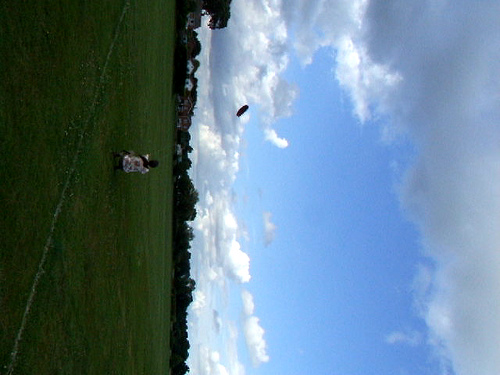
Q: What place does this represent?
A: It represents the field.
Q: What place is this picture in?
A: It is at the field.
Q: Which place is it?
A: It is a field.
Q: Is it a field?
A: Yes, it is a field.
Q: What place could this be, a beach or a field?
A: It is a field.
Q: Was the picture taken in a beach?
A: No, the picture was taken in a field.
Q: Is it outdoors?
A: Yes, it is outdoors.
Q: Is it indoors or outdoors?
A: It is outdoors.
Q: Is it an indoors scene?
A: No, it is outdoors.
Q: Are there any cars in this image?
A: No, there are no cars.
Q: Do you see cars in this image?
A: No, there are no cars.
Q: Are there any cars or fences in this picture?
A: No, there are no cars or fences.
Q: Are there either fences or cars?
A: No, there are no cars or fences.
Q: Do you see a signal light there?
A: No, there are no traffic lights.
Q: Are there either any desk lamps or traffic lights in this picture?
A: No, there are no traffic lights or desk lamps.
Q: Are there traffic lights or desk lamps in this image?
A: No, there are no traffic lights or desk lamps.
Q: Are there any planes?
A: No, there are no planes.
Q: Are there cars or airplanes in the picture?
A: No, there are no airplanes or cars.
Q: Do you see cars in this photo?
A: No, there are no cars.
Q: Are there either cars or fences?
A: No, there are no cars or fences.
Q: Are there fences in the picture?
A: No, there are no fences.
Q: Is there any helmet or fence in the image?
A: No, there are no fences or helmets.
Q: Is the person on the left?
A: Yes, the person is on the left of the image.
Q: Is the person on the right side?
A: No, the person is on the left of the image.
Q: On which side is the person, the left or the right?
A: The person is on the left of the image.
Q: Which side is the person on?
A: The person is on the left of the image.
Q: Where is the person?
A: The person is in the grass.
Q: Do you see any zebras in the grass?
A: No, there is a person in the grass.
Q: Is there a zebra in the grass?
A: No, there is a person in the grass.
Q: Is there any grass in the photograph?
A: Yes, there is grass.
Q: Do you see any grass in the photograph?
A: Yes, there is grass.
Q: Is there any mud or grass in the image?
A: Yes, there is grass.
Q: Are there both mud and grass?
A: No, there is grass but no mud.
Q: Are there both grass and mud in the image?
A: No, there is grass but no mud.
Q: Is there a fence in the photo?
A: No, there are no fences.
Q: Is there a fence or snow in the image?
A: No, there are no fences or snow.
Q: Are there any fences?
A: No, there are no fences.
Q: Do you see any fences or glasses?
A: No, there are no fences or glasses.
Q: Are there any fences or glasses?
A: No, there are no fences or glasses.